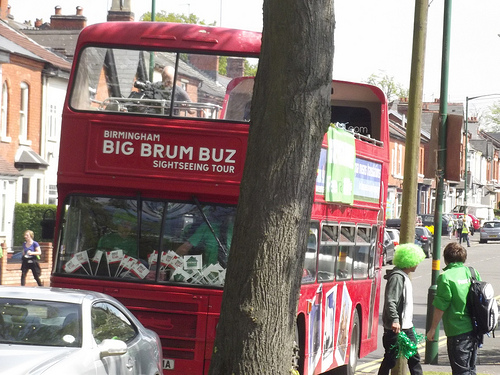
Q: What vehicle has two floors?
A: Double decker bus.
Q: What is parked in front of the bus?
A: Silver car.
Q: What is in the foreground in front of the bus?
A: Tree trunk.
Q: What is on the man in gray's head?
A: Green wig.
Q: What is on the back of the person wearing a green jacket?
A: Backpack.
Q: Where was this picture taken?
A: Birmingham.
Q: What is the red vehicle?
A: Double decker bus.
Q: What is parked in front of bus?
A: Silver sedan.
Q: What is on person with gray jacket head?
A: Green wig.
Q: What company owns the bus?
A: Big brum buz.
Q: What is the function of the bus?
A: Sightseeing.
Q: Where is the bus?
A: Parked at curb.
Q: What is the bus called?
A: Big Brum Buz.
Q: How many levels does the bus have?
A: Two.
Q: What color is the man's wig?
A: Green.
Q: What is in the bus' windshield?
A: Flags.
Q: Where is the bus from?
A: Birmingham.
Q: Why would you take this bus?
A: For a sightseeing tour.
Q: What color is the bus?
A: Red.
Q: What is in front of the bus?
A: A silver car.